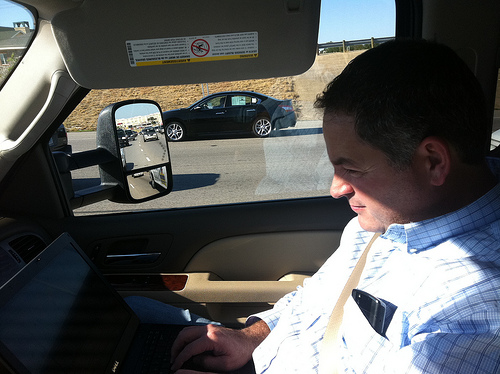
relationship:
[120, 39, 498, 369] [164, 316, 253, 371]
man has hand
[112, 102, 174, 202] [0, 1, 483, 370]
side mirror in car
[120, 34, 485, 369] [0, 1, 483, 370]
man sitting inside car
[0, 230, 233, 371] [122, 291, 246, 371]
laptop sitting on lap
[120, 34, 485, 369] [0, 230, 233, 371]
man working on laptop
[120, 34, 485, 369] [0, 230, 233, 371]
man using laptop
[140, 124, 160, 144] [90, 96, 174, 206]
car reflected in side mirror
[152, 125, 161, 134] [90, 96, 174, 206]
car reflected in side mirror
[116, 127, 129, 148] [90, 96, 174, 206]
car reflected in side mirror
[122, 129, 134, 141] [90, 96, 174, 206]
car reflected in side mirror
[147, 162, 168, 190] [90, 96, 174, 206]
car reflected in side mirror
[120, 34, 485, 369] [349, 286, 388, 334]
man carrying cell phone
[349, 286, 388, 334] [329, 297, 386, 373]
cell phone carried in pocket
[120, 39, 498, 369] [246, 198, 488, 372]
man wearing shirt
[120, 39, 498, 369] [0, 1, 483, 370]
man sitting in car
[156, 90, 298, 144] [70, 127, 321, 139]
car parked at curb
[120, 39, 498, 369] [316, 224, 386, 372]
man wearing belt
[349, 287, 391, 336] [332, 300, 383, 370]
cell phone in pocket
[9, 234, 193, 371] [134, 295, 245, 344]
laptop on lap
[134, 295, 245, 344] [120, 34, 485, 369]
lap of man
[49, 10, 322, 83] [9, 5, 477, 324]
visor on car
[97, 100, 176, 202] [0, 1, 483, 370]
side mirror on car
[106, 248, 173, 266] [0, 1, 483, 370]
handle on car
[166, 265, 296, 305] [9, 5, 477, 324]
arm rest on car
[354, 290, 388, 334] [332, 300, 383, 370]
cell phone in pocket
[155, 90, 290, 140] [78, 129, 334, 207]
car on street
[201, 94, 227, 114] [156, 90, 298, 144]
window on car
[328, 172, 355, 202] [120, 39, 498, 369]
nose on a man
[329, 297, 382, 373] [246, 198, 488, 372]
pocket on a shirt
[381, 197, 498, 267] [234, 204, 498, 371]
collar on shirt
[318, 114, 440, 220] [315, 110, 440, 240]
shadow on h face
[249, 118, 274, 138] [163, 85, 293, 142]
back tire of car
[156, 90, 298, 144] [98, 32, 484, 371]
car driving next to passenger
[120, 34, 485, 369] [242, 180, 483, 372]
man wearing shirt